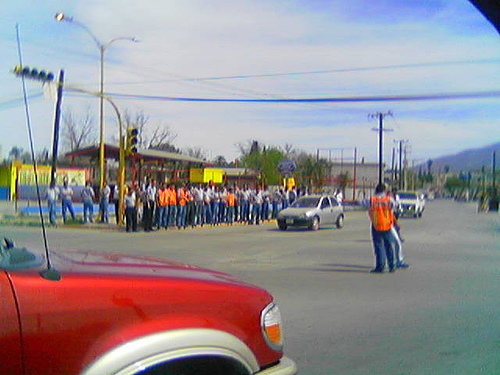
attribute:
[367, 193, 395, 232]
vest — orange, safety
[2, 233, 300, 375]
suv — red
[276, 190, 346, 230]
car — silver, subcompact, gray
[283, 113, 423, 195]
powerlines — wooden, brown, electric, hanging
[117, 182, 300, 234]
people — standing, along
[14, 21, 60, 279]
attenna — black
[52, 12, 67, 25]
headlight — white, orange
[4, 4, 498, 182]
sky — blue, white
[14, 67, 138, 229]
traffic signal — black, yellow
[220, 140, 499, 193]
leaves — green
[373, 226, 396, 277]
jeans — blue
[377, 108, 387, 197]
pole — utility, tall, wooden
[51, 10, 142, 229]
pole — double headed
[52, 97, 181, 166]
tree — bare, leafless